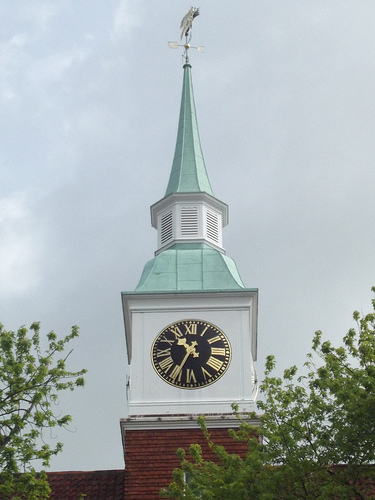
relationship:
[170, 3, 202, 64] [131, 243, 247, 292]
weather vane atop a cupola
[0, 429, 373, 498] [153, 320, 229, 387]
brick below a clock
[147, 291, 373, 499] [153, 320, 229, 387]
tree near clock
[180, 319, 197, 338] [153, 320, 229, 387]
roman numerals on clock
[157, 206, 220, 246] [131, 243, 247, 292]
air vents on cupola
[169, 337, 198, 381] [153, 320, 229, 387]
hands on clock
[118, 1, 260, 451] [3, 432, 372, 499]
top of building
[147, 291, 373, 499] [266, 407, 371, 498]
tree has branches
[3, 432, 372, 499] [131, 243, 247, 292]
building has shingles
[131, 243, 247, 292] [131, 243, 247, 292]
shingles on shingles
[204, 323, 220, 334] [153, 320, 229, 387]
gold marks on clock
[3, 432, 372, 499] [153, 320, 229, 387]
building has a clock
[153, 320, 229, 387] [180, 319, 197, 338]
clock has roman numerals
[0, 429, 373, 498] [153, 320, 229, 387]
brick below clock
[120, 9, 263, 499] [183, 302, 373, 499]
tower between tree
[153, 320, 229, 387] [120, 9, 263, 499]
clock on tower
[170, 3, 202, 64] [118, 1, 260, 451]
weather vane at top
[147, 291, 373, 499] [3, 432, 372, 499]
tree next to building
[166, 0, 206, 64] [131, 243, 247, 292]
weather vane atop cupola